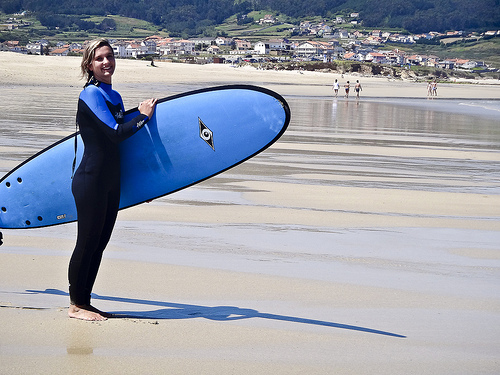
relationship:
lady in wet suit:
[60, 32, 164, 326] [60, 83, 143, 316]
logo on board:
[186, 114, 225, 162] [2, 87, 295, 234]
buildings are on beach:
[26, 13, 496, 78] [5, 62, 499, 361]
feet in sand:
[57, 297, 118, 326] [329, 193, 456, 247]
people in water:
[328, 76, 372, 104] [290, 97, 499, 178]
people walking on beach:
[409, 75, 447, 103] [5, 62, 499, 361]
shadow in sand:
[109, 282, 410, 352] [329, 193, 456, 247]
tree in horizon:
[36, 11, 95, 31] [1, 1, 493, 47]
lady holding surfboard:
[60, 32, 164, 326] [2, 87, 295, 234]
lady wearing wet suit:
[60, 32, 164, 326] [60, 83, 143, 316]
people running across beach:
[328, 76, 372, 104] [5, 62, 499, 361]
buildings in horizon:
[26, 13, 496, 78] [1, 1, 493, 47]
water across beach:
[290, 97, 499, 178] [5, 62, 499, 361]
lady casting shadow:
[60, 32, 164, 326] [109, 282, 410, 352]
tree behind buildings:
[36, 11, 95, 31] [26, 13, 496, 78]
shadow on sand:
[109, 282, 410, 352] [329, 193, 456, 247]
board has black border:
[2, 87, 295, 234] [226, 82, 271, 92]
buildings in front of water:
[26, 13, 496, 78] [290, 97, 499, 178]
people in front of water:
[328, 76, 372, 104] [290, 97, 499, 178]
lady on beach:
[60, 32, 164, 326] [5, 62, 499, 361]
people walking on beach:
[328, 76, 372, 104] [5, 62, 499, 361]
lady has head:
[60, 32, 164, 326] [82, 43, 120, 81]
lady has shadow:
[60, 32, 164, 326] [109, 282, 410, 352]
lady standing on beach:
[60, 32, 164, 326] [5, 62, 499, 361]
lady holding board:
[60, 32, 164, 326] [2, 87, 295, 234]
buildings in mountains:
[26, 13, 496, 78] [98, 9, 447, 34]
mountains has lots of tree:
[98, 9, 447, 34] [36, 11, 95, 31]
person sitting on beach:
[142, 53, 165, 70] [5, 62, 499, 361]